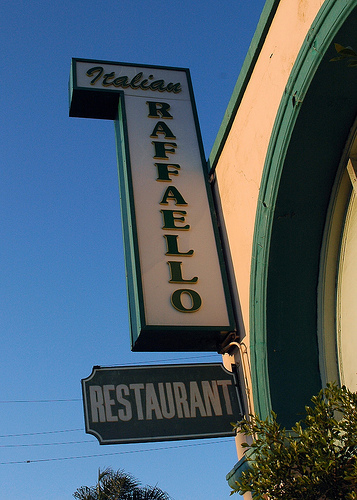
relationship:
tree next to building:
[230, 381, 356, 494] [207, 0, 353, 464]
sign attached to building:
[71, 51, 241, 351] [207, 0, 353, 464]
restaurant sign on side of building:
[71, 51, 241, 351] [207, 0, 353, 464]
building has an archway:
[207, 0, 353, 464] [229, 0, 355, 429]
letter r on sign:
[144, 93, 175, 124] [71, 51, 241, 351]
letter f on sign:
[151, 135, 181, 161] [71, 51, 241, 351]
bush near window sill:
[230, 381, 356, 494] [229, 0, 355, 429]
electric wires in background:
[0, 388, 233, 471] [0, 0, 254, 500]